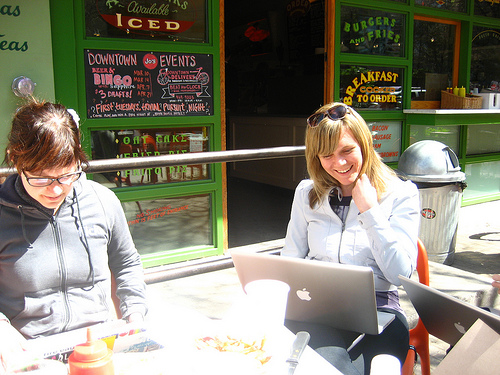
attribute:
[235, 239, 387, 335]
laptop — silver, open, grey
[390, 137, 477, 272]
garbage can — silver, metal, large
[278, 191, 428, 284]
jacket — white, zipped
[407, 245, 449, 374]
chair — orange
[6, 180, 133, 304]
hoodie — gray, zipped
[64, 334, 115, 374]
ketchup — bottle, red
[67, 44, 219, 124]
sign — painted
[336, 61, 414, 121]
sign — painted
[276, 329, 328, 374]
knife — black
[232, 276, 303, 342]
container — white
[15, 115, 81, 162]
hair — brown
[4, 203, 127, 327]
sweater — gray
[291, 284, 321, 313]
logo — apple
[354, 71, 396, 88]
letters — yellow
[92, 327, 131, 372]
bottle — squeezed, mustard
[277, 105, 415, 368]
woman — smiling, sitting, light skinned